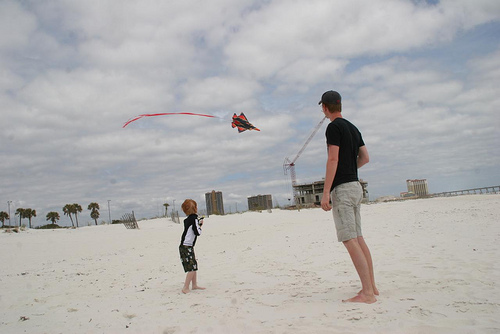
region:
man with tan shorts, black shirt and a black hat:
[316, 88, 383, 305]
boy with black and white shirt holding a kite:
[179, 197, 206, 292]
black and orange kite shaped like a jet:
[225, 110, 267, 136]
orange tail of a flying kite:
[119, 108, 221, 125]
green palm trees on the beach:
[1, 199, 106, 231]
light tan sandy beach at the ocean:
[9, 224, 493, 329]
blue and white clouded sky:
[5, 20, 494, 182]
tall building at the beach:
[200, 187, 227, 217]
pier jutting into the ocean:
[425, 183, 495, 200]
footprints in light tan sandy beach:
[290, 259, 438, 326]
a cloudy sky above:
[0, 0, 499, 227]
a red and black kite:
[122, 109, 261, 134]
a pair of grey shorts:
[329, 178, 364, 243]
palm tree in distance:
[87, 202, 100, 228]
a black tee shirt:
[322, 116, 365, 193]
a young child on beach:
[176, 196, 205, 293]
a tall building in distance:
[204, 187, 226, 216]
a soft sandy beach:
[0, 191, 499, 333]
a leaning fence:
[118, 212, 140, 229]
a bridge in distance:
[409, 184, 499, 196]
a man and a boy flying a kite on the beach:
[178, 90, 379, 307]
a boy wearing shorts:
[178, 245, 199, 271]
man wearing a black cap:
[318, 88, 343, 103]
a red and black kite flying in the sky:
[121, 110, 259, 134]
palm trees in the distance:
[0, 202, 102, 227]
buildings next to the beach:
[204, 185, 272, 212]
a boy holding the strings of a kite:
[195, 213, 206, 230]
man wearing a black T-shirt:
[326, 117, 365, 186]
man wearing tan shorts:
[330, 178, 363, 243]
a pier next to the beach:
[436, 185, 498, 194]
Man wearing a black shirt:
[298, 80, 391, 307]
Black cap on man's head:
[310, 80, 347, 118]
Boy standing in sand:
[165, 192, 213, 293]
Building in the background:
[395, 167, 431, 203]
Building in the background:
[282, 175, 368, 211]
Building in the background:
[237, 187, 278, 215]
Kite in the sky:
[111, 100, 267, 150]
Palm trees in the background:
[55, 197, 81, 227]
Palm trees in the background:
[12, 200, 40, 231]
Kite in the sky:
[199, 110, 289, 149]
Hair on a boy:
[180, 189, 216, 221]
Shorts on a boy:
[171, 238, 217, 281]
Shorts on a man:
[321, 175, 379, 247]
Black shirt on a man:
[320, 107, 367, 180]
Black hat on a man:
[311, 74, 350, 119]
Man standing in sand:
[291, 75, 410, 299]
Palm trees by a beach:
[35, 174, 130, 259]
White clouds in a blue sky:
[60, 65, 244, 165]